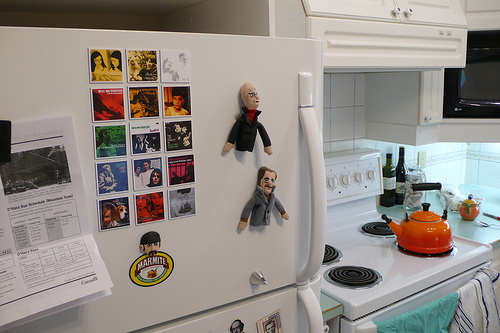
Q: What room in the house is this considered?
A: The kitchen.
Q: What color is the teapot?
A: Orange.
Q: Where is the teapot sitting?
A: On the stove.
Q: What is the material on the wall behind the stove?
A: Tile.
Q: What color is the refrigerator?
A: White.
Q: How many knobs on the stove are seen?
A: 4.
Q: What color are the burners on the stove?
A: Black.